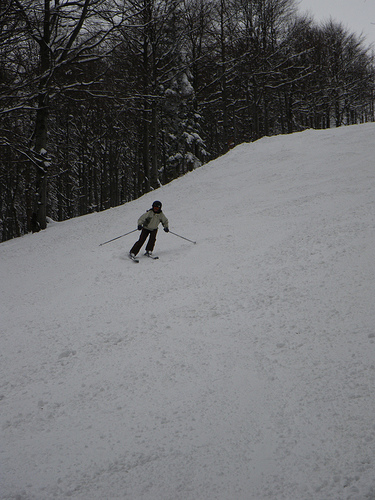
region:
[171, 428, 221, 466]
part of some holes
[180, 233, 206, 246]
part of a hooker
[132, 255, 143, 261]
edge of a board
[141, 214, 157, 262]
part of a trouser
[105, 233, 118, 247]
part of a hooker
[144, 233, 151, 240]
part of a trouser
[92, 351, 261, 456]
The snow is white.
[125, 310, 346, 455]
The snow is white.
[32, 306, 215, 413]
The snow is white.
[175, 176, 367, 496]
snow is covered on ground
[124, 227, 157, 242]
skier has black pants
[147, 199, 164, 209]
skier head turned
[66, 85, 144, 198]
trees in background of photo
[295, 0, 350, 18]
sky is gray and cloudy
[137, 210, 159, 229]
skier has white jacket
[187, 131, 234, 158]
white caps on trees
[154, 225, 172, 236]
skier wearing gloves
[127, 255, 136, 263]
skier has white boots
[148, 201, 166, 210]
skier has goggles on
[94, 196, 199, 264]
A man skiing down a snowy hill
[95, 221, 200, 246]
Two ski poles held out to the sides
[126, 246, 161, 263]
Grey skiis worn by the skier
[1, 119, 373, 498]
A snowy hill that a man is skiing down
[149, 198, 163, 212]
A black helmet worn by the man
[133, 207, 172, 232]
A puffy white jacket worn by the man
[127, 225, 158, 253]
Black pants worn by the man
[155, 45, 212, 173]
A particularly snow-covered tree behind the hill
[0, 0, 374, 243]
A wall of dark, bare trees in the background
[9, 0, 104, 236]
A tree with a thick trunk nearest the man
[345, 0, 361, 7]
part of the sky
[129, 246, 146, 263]
edge of a board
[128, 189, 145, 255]
part of a trouser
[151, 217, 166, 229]
part of a jacket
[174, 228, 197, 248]
part of a hooker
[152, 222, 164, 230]
part of a jacket